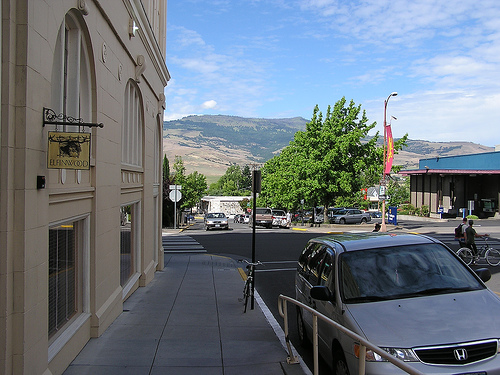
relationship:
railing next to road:
[276, 294, 424, 374] [163, 233, 499, 369]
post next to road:
[252, 170, 261, 309] [163, 233, 499, 369]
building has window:
[1, 4, 170, 374] [48, 219, 85, 343]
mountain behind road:
[164, 116, 498, 185] [163, 233, 499, 369]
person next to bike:
[466, 221, 481, 257] [455, 235, 498, 265]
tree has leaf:
[294, 99, 407, 221] [339, 122, 340, 123]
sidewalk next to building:
[63, 252, 309, 373] [1, 4, 170, 374]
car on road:
[295, 231, 499, 369] [163, 233, 499, 369]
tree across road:
[294, 99, 407, 221] [163, 233, 499, 369]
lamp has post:
[386, 92, 400, 104] [383, 107, 386, 232]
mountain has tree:
[164, 116, 498, 185] [231, 135, 234, 140]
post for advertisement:
[383, 107, 386, 232] [384, 124, 393, 174]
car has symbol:
[295, 231, 499, 369] [456, 347, 466, 361]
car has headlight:
[295, 231, 499, 369] [356, 346, 416, 361]